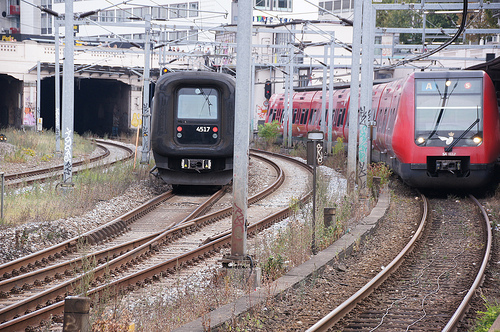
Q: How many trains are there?
A: Two.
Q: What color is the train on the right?
A: Red.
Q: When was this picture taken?
A: Daytime.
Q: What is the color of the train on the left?
A: Black.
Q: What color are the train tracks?
A: Brown.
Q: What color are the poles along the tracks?
A: White.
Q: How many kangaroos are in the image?
A: Zero.